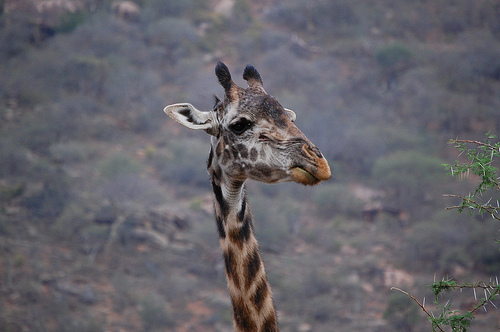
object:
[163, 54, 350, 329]
giraffe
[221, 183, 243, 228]
patch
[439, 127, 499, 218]
leaves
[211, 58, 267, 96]
horns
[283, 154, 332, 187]
mouth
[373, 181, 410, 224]
ground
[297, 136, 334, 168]
nose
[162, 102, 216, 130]
ear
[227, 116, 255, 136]
eye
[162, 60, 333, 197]
television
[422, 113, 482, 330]
tree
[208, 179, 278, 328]
neck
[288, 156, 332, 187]
closed mouth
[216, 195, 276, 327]
spots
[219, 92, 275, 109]
forehead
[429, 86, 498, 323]
tree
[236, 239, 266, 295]
spot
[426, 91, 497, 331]
tree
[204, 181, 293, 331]
throat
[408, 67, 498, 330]
trees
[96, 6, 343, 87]
terraine